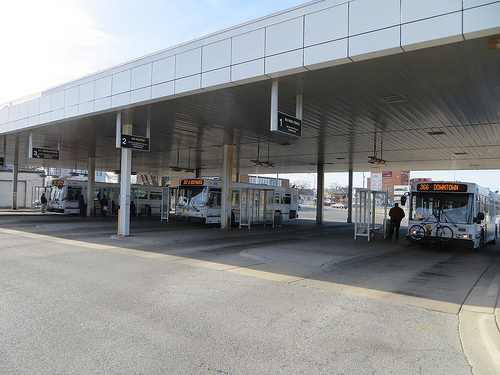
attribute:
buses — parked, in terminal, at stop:
[62, 178, 498, 277]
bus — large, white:
[400, 173, 497, 265]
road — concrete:
[121, 248, 337, 373]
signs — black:
[34, 102, 302, 162]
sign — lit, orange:
[418, 178, 462, 196]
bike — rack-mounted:
[404, 214, 467, 245]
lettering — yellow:
[415, 179, 458, 190]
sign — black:
[267, 98, 308, 137]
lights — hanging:
[254, 121, 387, 175]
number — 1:
[269, 111, 293, 139]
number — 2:
[118, 134, 129, 148]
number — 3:
[29, 147, 42, 158]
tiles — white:
[7, 22, 268, 132]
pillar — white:
[111, 131, 142, 235]